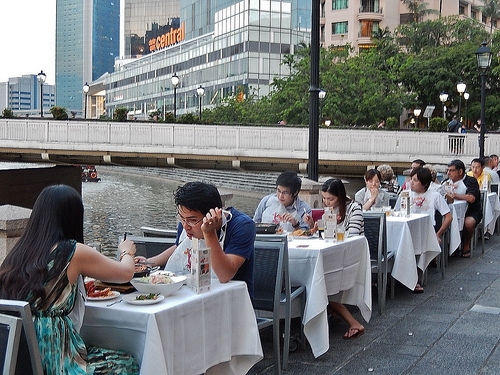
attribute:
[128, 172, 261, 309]
man — asian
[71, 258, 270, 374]
table — clean, small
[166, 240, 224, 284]
napkin — large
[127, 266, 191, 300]
bowl — porcelain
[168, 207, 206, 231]
glasses — brown, clear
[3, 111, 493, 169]
bridge — long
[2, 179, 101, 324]
hair — long, beautiful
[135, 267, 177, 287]
rice — white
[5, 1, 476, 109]
buildings — tall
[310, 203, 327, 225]
menu — red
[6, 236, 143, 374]
dress — green, white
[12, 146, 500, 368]
outdoors — outdoor, asian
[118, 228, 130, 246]
chop sticks — black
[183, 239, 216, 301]
menu — open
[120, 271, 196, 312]
dishes — white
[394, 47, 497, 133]
lights — white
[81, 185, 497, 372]
tablecloths — white